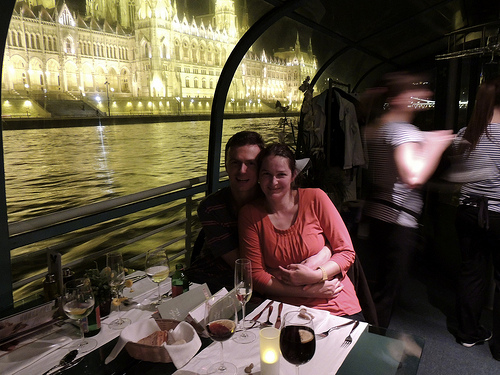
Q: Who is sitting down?
A: The people.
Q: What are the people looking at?
A: The camera.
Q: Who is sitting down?
A: The people.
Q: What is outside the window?
A: A building.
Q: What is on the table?
A: Glasses.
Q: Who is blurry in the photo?
A: A girl.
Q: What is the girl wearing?
A: An orange shirt.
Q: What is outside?
A: The calm river.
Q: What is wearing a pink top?
A: The woman.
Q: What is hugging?
A: The man and woman.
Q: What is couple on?
A: Cruise.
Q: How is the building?
A: Lit.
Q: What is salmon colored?
A: Shirt.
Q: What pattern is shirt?
A: Striped.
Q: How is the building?
A: Lit.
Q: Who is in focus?
A: A man and woman.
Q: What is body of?
A: Water.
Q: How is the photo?
A: Blurry.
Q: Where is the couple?
A: Restaurant.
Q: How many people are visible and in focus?
A: Four.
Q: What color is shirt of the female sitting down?
A: Pink.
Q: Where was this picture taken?
A: A boat.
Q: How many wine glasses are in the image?
A: Six.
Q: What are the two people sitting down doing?
A: Hugging.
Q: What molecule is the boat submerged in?
A: H2O.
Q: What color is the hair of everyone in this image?
A: Brown.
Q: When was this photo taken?
A: Night time.